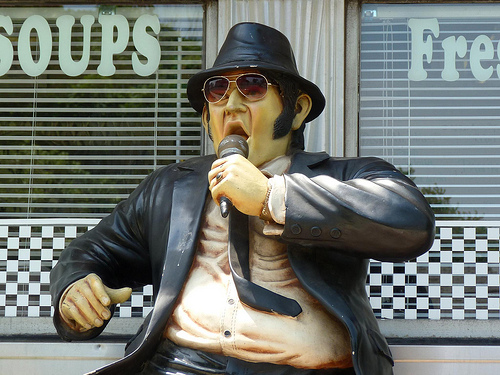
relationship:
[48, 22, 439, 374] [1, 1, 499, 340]
statue in front of restaraunt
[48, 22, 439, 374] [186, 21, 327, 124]
statue has hat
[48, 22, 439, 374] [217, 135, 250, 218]
statue holding microphone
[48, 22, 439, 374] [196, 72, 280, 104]
statue wearing sunglasses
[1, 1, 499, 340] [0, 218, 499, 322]
restaraunt has tiles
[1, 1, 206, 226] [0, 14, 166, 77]
window with words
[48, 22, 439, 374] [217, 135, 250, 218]
statue with microphone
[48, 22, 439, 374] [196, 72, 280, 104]
statue with sunglasses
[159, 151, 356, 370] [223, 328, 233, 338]
shirt has button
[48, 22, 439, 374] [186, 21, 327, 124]
statue wearing hat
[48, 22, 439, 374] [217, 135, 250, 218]
statue has microphone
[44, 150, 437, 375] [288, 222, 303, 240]
jacket has button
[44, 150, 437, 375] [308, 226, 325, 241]
jacket has button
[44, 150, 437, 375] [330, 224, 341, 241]
jacket has button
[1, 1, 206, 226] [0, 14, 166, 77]
window has words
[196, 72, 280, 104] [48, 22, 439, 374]
sunglasses on statue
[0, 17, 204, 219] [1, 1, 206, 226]
blinds in window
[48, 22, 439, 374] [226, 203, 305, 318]
statue wearing tie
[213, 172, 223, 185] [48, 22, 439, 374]
ring on statue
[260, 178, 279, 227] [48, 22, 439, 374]
watch on statue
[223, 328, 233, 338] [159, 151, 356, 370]
button on shirt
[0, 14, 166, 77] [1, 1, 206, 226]
words on window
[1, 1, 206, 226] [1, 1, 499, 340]
window on restaraunt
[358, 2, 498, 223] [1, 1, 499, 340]
window on restaraunt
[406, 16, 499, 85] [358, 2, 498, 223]
words on window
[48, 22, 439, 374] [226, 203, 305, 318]
statue has tie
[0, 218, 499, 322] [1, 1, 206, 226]
tiles under window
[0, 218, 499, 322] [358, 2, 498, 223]
tiles under window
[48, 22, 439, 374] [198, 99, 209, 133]
statue has ear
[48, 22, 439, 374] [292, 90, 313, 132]
statue has ear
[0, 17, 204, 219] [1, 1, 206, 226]
blinds behind window